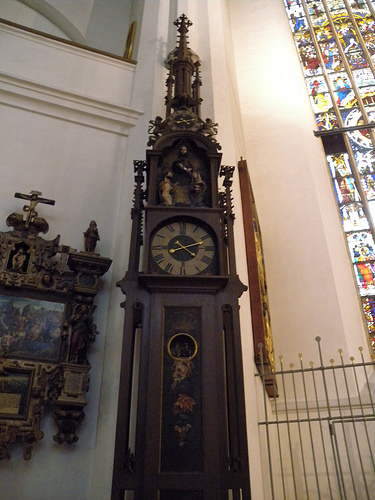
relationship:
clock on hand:
[146, 216, 218, 276] [168, 237, 192, 259]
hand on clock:
[168, 243, 197, 265] [122, 196, 259, 292]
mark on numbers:
[177, 240, 215, 254] [140, 243, 210, 274]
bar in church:
[251, 332, 373, 497] [14, 6, 359, 367]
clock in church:
[146, 216, 218, 276] [47, 20, 319, 489]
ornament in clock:
[144, 139, 201, 194] [100, 55, 245, 440]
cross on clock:
[160, 12, 190, 67] [85, 84, 275, 375]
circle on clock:
[170, 329, 215, 363] [112, 49, 266, 473]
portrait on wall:
[3, 291, 59, 358] [8, 102, 113, 468]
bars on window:
[300, 37, 373, 95] [275, 14, 373, 167]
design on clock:
[154, 300, 231, 469] [128, 68, 275, 457]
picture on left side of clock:
[231, 152, 282, 404] [144, 218, 217, 276]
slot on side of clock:
[121, 292, 141, 465] [149, 212, 217, 276]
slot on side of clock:
[218, 302, 241, 471] [149, 212, 217, 276]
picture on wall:
[236, 156, 287, 404] [206, 6, 291, 498]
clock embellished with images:
[110, 8, 250, 497] [131, 100, 225, 145]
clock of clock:
[146, 216, 218, 276] [142, 207, 227, 336]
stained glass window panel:
[252, 238, 373, 407] [314, 243, 372, 330]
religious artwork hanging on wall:
[9, 166, 107, 428] [15, 273, 120, 467]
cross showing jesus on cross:
[0, 183, 63, 212] [15, 168, 58, 279]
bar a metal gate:
[251, 332, 373, 497] [229, 425, 366, 437]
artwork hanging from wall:
[229, 251, 291, 352] [253, 356, 291, 433]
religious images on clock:
[152, 172, 211, 236] [146, 247, 208, 313]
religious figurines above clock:
[154, 142, 209, 211] [149, 216, 219, 278]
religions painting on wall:
[3, 185, 103, 461] [3, 7, 217, 499]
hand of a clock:
[168, 237, 201, 262] [149, 219, 214, 277]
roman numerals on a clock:
[149, 219, 213, 280] [144, 218, 217, 276]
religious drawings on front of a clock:
[161, 305, 204, 471] [97, 13, 270, 498]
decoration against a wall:
[254, 333, 373, 499] [214, 1, 373, 497]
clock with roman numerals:
[146, 216, 218, 276] [150, 221, 220, 276]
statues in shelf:
[158, 156, 207, 202] [150, 201, 225, 207]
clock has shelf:
[110, 8, 250, 497] [150, 201, 225, 207]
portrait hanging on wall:
[3, 291, 59, 358] [1, 100, 116, 490]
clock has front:
[110, 8, 250, 497] [144, 297, 222, 472]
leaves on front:
[173, 394, 196, 411] [144, 297, 222, 472]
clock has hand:
[149, 216, 219, 278] [173, 242, 198, 253]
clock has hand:
[149, 216, 219, 278] [177, 242, 194, 255]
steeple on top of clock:
[160, 6, 211, 123] [110, 8, 250, 497]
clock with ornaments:
[110, 8, 250, 497] [149, 108, 217, 140]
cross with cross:
[7, 183, 69, 238] [0, 183, 63, 212]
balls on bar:
[251, 330, 373, 368] [249, 329, 374, 491]